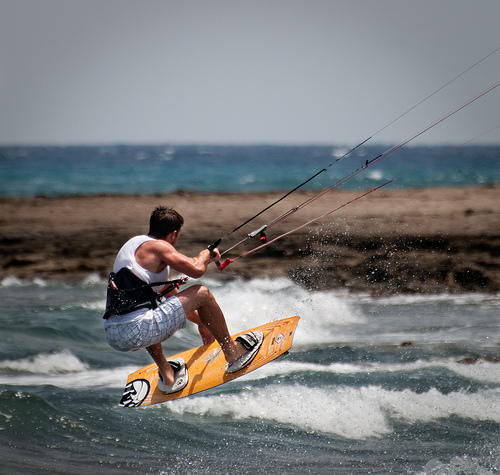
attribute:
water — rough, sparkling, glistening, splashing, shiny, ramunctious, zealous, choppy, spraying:
[271, 374, 397, 440]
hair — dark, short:
[150, 203, 181, 230]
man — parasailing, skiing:
[100, 187, 240, 378]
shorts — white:
[102, 307, 187, 347]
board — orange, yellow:
[91, 313, 303, 403]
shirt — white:
[105, 228, 169, 282]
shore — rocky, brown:
[318, 234, 430, 296]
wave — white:
[16, 349, 87, 374]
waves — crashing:
[292, 285, 456, 431]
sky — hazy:
[61, 7, 473, 114]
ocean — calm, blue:
[15, 286, 490, 462]